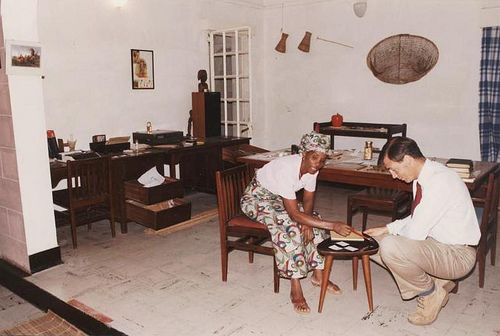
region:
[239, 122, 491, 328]
man and woman examining item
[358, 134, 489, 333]
man examining item with woman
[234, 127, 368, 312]
woman examining item with man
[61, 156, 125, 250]
wooden chair at desk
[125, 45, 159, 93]
image on the wall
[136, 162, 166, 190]
paper resting in drawer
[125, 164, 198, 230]
two opened drawers with items inside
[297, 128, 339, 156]
wrap on woman's head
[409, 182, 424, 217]
tie on man's neck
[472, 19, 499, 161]
curtain on the wall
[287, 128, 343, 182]
Woman wearing a floral bonnet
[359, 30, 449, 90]
Basket mounted on the wall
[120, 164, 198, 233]
Open drawers containing papers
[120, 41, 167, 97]
Picture mounted on the wall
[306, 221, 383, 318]
Stool with papers on it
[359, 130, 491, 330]
Man crouched in front of small stool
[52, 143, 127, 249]
Chair under a work desk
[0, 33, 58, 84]
Photo placed on wall corner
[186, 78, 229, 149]
Speaker in corner of the room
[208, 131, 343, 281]
Woman sitting on a chair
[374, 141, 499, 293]
MAN IN WHITE SHIRT BENDING FORWARD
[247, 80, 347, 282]
WOMAN WITH WHITE SHIRT BENDING OVER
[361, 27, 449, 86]
LARGE SPREAD FAN ON WALL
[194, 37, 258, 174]
DOOR IN BACKGROUND WITH WINDOW PANES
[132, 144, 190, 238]
WOODEN DRAWERS PULLED OPEN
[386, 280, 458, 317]
TAN BOOTS ON MAN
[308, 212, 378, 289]
SMALL TABLE BETWEEN TWO PEOPLE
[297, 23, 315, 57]
SMALL OBJECTS ON WALL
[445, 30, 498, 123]
BLUE CURTAINS ON RIGHT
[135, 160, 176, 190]
WHITE PAPER IN DRAWERS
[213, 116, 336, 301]
woman sitting on wooden chair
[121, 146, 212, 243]
the drawers are open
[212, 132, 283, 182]
the drawers are open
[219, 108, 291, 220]
the drawers are open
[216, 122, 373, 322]
Black woman chair takes notes.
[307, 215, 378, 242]
Pencil woman's right hand.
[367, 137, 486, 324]
Man kneeling front three legged stool.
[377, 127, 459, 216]
Man short brown hair cut red tie.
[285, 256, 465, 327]
Bare feet vs. shod feet.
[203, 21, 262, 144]
French door many glass panes.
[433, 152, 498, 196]
Three books stacked table end.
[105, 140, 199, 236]
Desk drawer's pulled open.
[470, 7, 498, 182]
Blue plaid curtains cover window.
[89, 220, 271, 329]
Well used tan tile floor.